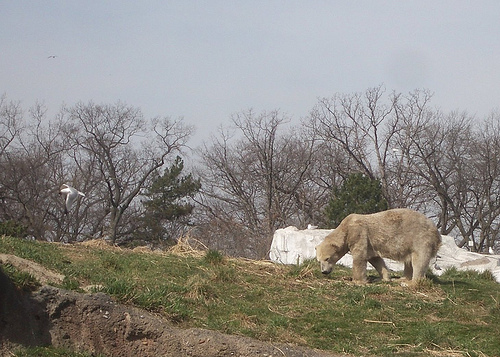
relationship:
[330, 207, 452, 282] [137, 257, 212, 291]
bear in field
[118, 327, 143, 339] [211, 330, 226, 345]
dirt on ground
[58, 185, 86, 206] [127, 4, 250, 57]
bird in sky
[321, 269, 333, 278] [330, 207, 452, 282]
nose of bear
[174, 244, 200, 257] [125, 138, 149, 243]
straw under tree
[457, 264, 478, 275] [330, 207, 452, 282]
snow behind bear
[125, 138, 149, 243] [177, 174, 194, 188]
tree has leaves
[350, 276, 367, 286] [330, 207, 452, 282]
paw of bear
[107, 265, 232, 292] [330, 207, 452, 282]
grass under bear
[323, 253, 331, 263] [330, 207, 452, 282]
eye of bear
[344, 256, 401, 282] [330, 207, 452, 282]
legs of bear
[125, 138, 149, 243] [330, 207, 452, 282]
tree near bear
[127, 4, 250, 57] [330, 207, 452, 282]
sky above bear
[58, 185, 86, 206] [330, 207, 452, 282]
bird near bear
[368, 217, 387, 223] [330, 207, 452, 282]
fur of bear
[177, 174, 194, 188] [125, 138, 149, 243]
leaves of tree